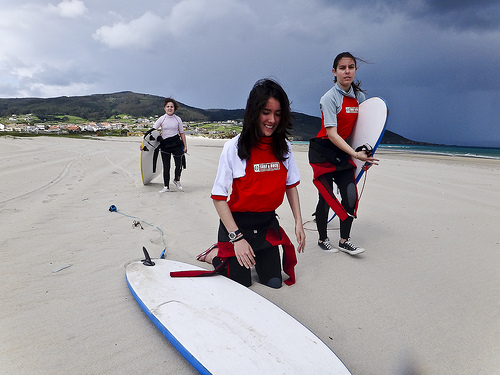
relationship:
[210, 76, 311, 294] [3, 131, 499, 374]
girl in sand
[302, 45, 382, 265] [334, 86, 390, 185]
girl holding surfboard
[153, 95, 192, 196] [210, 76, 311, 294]
woman watching girl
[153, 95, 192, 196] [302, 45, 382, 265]
woman watching girl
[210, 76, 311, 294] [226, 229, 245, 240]
girl wearing watch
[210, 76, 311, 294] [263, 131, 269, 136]
girl has mole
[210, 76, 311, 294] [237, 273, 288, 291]
girl on knees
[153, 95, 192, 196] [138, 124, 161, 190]
woman drags surfboard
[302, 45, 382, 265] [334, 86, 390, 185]
girl holds surfboard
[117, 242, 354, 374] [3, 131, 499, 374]
surfboard on sand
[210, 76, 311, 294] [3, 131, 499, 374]
girl on sand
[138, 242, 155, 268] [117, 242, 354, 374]
fin on surfboard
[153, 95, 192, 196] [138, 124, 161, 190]
woman dragging surfboard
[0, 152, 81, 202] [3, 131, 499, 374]
marks in sand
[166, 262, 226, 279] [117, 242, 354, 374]
strap on surfboard